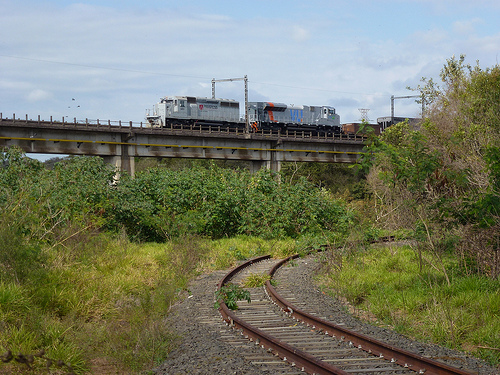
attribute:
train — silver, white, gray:
[144, 94, 424, 135]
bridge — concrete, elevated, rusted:
[1, 113, 377, 181]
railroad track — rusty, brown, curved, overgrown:
[219, 251, 434, 372]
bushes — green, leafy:
[110, 165, 358, 240]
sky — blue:
[1, 3, 500, 124]